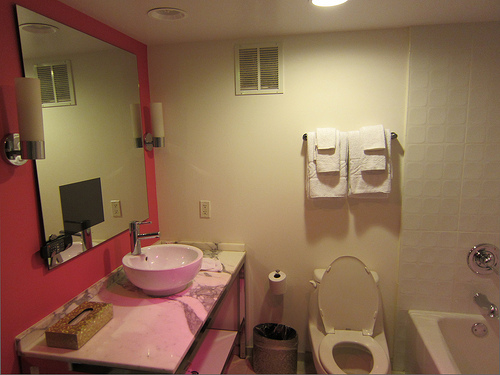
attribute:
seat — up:
[311, 254, 381, 337]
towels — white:
[295, 129, 400, 204]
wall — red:
[148, 21, 499, 371]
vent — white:
[229, 36, 292, 106]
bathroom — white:
[2, 2, 499, 369]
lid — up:
[315, 252, 381, 341]